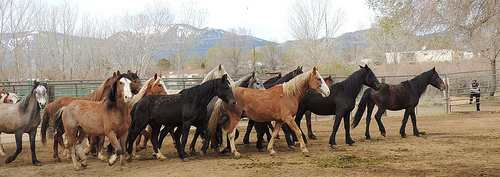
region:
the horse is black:
[329, 70, 379, 143]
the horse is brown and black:
[381, 67, 453, 141]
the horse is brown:
[239, 72, 329, 162]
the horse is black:
[134, 84, 243, 160]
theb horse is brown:
[60, 69, 146, 176]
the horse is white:
[6, 79, 53, 139]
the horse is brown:
[145, 71, 173, 92]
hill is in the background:
[108, 14, 280, 63]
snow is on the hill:
[143, 19, 197, 37]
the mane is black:
[182, 77, 227, 107]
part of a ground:
[396, 150, 404, 160]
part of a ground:
[346, 143, 361, 163]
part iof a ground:
[401, 138, 407, 145]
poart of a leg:
[298, 142, 306, 157]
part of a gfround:
[392, 133, 402, 149]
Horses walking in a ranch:
[1, 66, 445, 158]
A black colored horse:
[127, 74, 235, 162]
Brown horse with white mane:
[206, 67, 331, 158]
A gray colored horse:
[0, 80, 52, 170]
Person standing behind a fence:
[466, 78, 484, 108]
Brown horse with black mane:
[63, 70, 133, 164]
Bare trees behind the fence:
[1, 0, 499, 74]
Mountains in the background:
[0, 19, 499, 58]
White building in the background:
[390, 48, 482, 62]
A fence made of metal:
[398, 70, 499, 105]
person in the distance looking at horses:
[468, 79, 480, 111]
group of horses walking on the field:
[1, 61, 448, 168]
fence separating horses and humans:
[2, 69, 497, 126]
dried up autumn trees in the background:
[4, 5, 495, 105]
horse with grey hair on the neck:
[1, 81, 52, 163]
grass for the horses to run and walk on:
[0, 106, 498, 174]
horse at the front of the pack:
[350, 63, 447, 140]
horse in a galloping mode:
[42, 68, 136, 175]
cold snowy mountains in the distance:
[1, 18, 491, 80]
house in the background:
[371, 45, 495, 69]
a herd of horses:
[1, 59, 474, 174]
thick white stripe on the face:
[318, 71, 331, 96]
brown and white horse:
[52, 68, 149, 175]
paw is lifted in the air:
[106, 143, 121, 169]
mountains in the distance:
[0, 21, 273, 73]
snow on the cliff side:
[2, 30, 50, 55]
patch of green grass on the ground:
[312, 147, 372, 168]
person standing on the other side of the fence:
[445, 69, 497, 119]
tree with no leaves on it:
[283, 0, 346, 73]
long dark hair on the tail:
[346, 89, 372, 130]